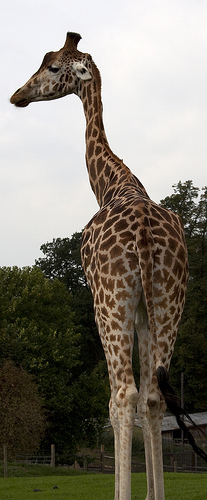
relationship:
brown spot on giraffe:
[69, 76, 73, 80] [8, 31, 191, 498]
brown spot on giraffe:
[94, 95, 98, 113] [8, 31, 191, 498]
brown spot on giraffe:
[82, 100, 87, 109] [8, 31, 191, 498]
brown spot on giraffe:
[92, 127, 97, 134] [8, 31, 191, 498]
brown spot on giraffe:
[95, 146, 102, 155] [8, 31, 191, 498]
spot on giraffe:
[51, 79, 56, 85] [9, 31, 189, 349]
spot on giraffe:
[82, 105, 96, 114] [11, 24, 200, 261]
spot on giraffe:
[86, 119, 96, 136] [11, 27, 164, 197]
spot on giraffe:
[93, 144, 100, 154] [8, 31, 191, 498]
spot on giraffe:
[87, 158, 97, 181] [8, 31, 191, 498]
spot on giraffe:
[94, 156, 106, 174] [8, 31, 191, 498]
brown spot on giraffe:
[127, 213, 135, 221] [8, 31, 191, 498]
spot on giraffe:
[151, 266, 176, 293] [39, 40, 206, 249]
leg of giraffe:
[116, 394, 135, 499] [8, 31, 191, 498]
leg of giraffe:
[108, 401, 121, 499] [8, 31, 191, 498]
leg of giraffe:
[138, 383, 156, 498] [8, 31, 191, 498]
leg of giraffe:
[147, 394, 167, 499] [8, 31, 191, 498]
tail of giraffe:
[135, 226, 205, 462] [8, 31, 191, 498]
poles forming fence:
[1, 443, 55, 475] [0, 437, 107, 473]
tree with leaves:
[7, 232, 82, 364] [3, 265, 79, 364]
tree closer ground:
[1, 357, 44, 467] [3, 473, 200, 497]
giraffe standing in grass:
[8, 31, 190, 499] [3, 473, 205, 497]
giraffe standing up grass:
[8, 31, 191, 498] [3, 470, 204, 498]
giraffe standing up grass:
[8, 31, 190, 499] [14, 453, 183, 497]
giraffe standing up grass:
[8, 31, 190, 499] [26, 472, 174, 497]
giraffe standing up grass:
[8, 31, 190, 499] [3, 464, 204, 498]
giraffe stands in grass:
[8, 31, 191, 498] [67, 472, 111, 497]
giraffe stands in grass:
[8, 31, 191, 498] [1, 461, 205, 497]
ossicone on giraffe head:
[62, 27, 78, 51] [8, 31, 90, 108]